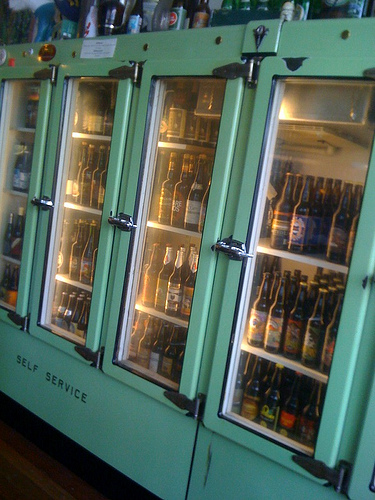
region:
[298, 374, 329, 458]
This is a bottle of alcohol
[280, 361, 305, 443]
This is a bottle of alcohol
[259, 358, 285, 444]
This is a bottle of alcohol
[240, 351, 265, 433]
This is a bottle of alcohol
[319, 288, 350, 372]
This is a bottle of alcohol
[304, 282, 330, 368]
This is a bottle of alcohol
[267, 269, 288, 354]
This is a bottle of alcohol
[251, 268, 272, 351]
This is a bottle of alcohol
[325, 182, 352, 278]
This is a bottle of alcohol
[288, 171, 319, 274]
This is a bottle of alcohol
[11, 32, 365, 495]
cooler full of beer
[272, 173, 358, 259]
beer bottles on a shelf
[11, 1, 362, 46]
bottles sitting on top of a cooler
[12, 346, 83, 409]
black letters on the cooler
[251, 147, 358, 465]
three shelves of beer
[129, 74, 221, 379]
four shelves of beer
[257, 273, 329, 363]
dark brown beer bottles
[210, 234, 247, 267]
big silver hinge of a cooler door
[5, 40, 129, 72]
stickers and labels on the cooler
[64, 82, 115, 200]
lights inside the cooler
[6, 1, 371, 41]
Bottles on top of cooler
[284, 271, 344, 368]
Brown bottles with gold colored lids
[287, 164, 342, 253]
Brown bottles with blue and white labels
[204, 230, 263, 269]
Silver colored handle on a cooler door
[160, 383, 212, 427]
Hinge on a cooler door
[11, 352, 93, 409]
The words Self Service on the front of a cooler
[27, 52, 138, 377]
Door with a glass front on a cooler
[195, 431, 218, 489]
Scuff mark on the front of a cooler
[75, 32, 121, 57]
White sign on the front of a cooler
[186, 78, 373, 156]
Cooling unit inside cooler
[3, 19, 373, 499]
green metal refrigerated case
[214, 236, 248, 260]
silver metal refridgerator handle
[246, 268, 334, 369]
beer bottles on shelf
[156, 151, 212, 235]
glass bottles on shelf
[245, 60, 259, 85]
grey metal hinge on door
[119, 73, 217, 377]
glass window on door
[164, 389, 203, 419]
black metal hinge on door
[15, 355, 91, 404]
black letters on door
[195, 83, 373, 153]
silver refrigerator fan in case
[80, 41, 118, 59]
white paper on refrigerator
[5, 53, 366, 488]
a cupboard full of bottles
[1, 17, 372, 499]
the cabinet is green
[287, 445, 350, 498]
the hinge is black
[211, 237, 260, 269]
the door is locked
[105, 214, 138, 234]
this door is locked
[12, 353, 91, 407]
letters on the cabinet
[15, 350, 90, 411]
the letters are black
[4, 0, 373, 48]
bottles on top of the cabinet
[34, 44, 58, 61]
a gold seal on the cabinet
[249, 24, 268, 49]
a keyhole on the cabinet